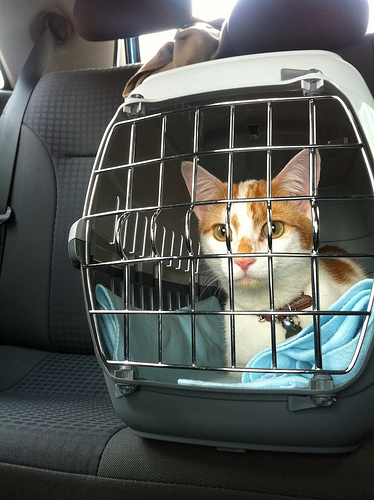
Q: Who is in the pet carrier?
A: The cat.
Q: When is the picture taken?
A: Daytime.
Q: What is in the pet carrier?
A: A cat.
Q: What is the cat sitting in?
A: A pet carrier.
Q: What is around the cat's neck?
A: A collar.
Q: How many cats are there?
A: One.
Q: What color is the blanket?
A: Blue.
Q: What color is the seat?
A: Gray.